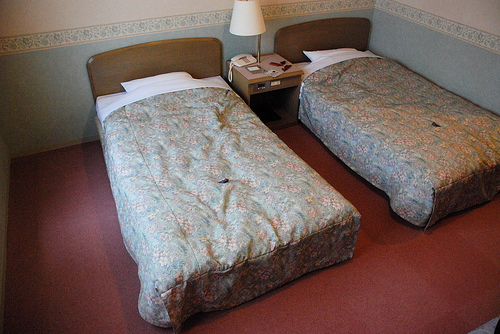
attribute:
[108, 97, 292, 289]
bed spread — floral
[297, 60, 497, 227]
sheet — blue, pink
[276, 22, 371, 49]
board — wood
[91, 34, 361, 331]
bed — floral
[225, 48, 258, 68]
phone — white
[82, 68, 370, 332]
bed spread — floral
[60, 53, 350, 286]
bed — floral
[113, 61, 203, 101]
pillow — white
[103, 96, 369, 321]
bed spread — floral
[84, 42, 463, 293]
left side — pink, blue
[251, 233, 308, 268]
spread — floral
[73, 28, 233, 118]
headboard — wooden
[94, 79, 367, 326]
bedspread — flowered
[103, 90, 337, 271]
bed spread — floral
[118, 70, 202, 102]
pillow — white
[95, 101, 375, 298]
sheets — flowery